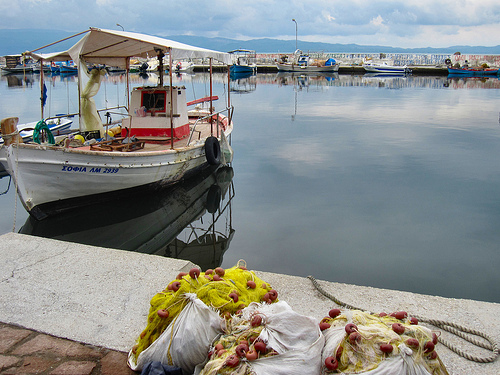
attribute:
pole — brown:
[205, 59, 212, 134]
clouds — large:
[223, 0, 398, 38]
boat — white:
[3, 22, 243, 210]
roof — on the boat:
[25, 25, 232, 65]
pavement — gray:
[8, 218, 493, 363]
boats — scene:
[9, 36, 481, 301]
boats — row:
[2, 42, 491, 102]